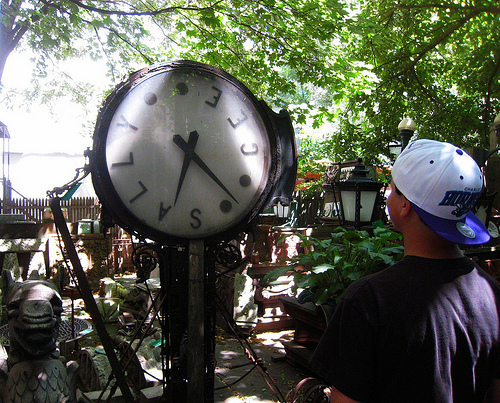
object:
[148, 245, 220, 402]
clock has a pole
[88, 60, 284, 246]
clock is large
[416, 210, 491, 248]
cap has purple bill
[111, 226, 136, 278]
fence is wooden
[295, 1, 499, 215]
there is an oak tree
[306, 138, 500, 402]
there is a man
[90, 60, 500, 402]
man looking at clock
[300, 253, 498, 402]
there is a shirt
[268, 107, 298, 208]
clock has parts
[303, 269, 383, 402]
there is shirts part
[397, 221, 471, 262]
boy has a neck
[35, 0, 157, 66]
there is tree branch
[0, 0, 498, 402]
there is a snap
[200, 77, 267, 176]
surface has a part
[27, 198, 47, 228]
fence has a part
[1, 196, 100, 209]
fence has top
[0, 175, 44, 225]
there is a stair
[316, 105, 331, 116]
leafs are green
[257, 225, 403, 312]
there is a plant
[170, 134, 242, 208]
black clock hands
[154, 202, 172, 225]
there is a letter a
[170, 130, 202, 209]
clock has a hand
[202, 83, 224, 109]
letters are black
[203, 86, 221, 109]
letter is black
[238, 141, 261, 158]
letter is black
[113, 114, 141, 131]
letter is black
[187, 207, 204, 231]
letter is black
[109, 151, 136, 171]
letter is black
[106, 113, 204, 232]
word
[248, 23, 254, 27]
leaves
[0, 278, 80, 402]
sculpture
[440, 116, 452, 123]
leaves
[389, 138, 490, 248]
hat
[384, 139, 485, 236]
head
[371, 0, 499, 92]
branches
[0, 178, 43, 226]
stair railing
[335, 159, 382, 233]
lantern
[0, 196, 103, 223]
picket fence